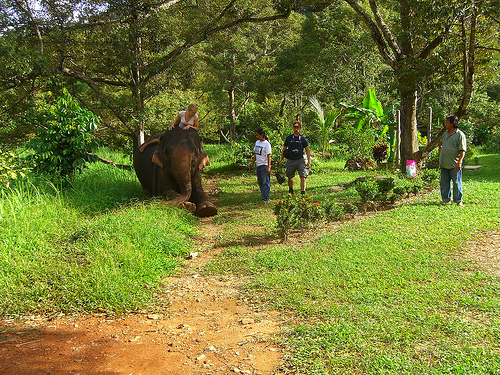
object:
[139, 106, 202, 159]
woman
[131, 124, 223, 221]
elephant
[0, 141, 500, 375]
grass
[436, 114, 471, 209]
man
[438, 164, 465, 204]
jeans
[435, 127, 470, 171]
shirt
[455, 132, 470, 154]
sleeve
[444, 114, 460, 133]
hair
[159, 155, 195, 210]
trunk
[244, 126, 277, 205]
woman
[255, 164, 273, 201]
jeans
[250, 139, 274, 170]
shirt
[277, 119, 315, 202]
man